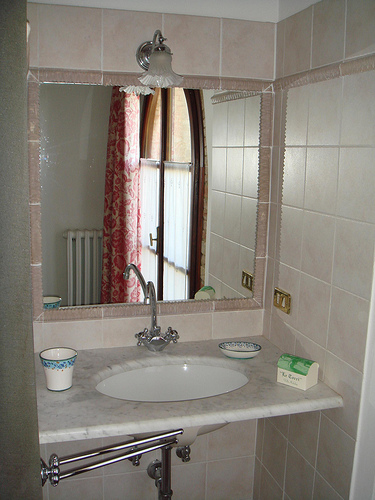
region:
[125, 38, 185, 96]
frosted light over sink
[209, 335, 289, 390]
white dish near sink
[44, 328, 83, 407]
blue and white cup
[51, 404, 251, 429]
sink is white and black marble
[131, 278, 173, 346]
nickel faucet in sink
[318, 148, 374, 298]
white tile on wall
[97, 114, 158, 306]
red and gold curtain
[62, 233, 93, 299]
white radiator near curtain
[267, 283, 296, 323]
gold electrical outlet on wall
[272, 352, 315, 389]
green and white container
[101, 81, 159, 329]
red curtain by window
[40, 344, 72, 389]
blue and white cup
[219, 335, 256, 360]
blue and white soap dish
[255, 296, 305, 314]
gold electrical outlet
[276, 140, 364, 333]
white tile on wall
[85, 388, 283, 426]
black and white marble sink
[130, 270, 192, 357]
nickel finish on faucet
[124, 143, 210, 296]
white curtain on window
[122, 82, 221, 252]
brown frame on arched window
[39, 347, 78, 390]
cup on the sink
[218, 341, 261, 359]
small bowel on the sink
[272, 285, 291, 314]
electrical socket in the wall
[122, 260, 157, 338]
silver faucet in back of the sink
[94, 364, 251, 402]
oval white sink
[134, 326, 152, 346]
left knob of faucet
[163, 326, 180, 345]
left knob of faucet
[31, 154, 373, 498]
taupe colored wall tile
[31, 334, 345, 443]
taupe and white countertop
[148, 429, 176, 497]
pipes under the sink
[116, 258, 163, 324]
a faucet over a sink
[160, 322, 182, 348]
a right handle of faucet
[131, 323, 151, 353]
a left handle of faucet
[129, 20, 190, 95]
a lamp over a mirror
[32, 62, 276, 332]
a mirror above a sink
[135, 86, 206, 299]
a door reflected on a mirror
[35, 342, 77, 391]
a white and blue cup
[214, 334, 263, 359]
a dish soap on a counter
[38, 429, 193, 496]
pipes under a sink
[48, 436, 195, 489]
pipes are color silver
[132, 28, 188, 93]
A decorative white and silver glass light.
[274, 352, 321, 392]
A green and white box.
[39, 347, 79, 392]
A ceramic type cup for drinking water.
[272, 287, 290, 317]
Switches that control the lights.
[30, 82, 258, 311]
A bathroom vanity mirror.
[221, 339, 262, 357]
A ceramic type soap dish.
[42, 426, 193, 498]
Silver piping for the bathroom and sink.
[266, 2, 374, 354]
A section of pink bathroom tile on the right.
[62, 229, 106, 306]
A white radiator in the reflection of the mirror.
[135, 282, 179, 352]
A silver faucet and silver spout.